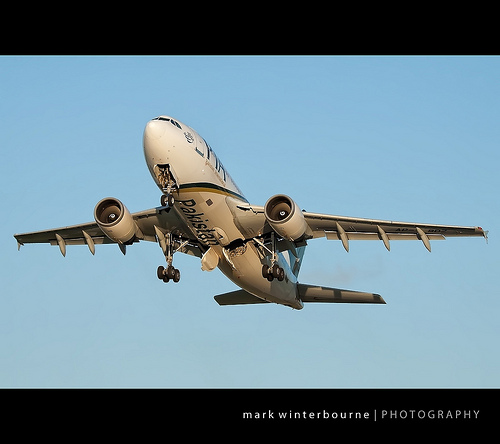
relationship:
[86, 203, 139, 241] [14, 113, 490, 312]
engine on plane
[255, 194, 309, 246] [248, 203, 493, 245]
engine by wing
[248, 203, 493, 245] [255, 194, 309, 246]
wing with engine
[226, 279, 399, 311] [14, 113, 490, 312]
tail on plane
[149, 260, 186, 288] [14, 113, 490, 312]
wheels on plane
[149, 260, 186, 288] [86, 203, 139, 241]
wheels by engine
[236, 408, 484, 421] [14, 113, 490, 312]
water on plane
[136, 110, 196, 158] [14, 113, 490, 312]
cockpit on plane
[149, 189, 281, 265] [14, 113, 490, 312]
belly of plane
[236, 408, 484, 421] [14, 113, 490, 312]
name by plane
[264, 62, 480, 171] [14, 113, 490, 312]
sky by plane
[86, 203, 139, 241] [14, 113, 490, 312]
engine of plane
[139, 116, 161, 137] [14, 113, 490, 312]
nose of plane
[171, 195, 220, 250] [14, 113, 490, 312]
name on plane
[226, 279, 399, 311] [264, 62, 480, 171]
tail by sky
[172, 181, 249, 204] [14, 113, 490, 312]
stripes on plane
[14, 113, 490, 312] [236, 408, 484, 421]
plane by water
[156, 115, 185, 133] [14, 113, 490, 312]
window by plane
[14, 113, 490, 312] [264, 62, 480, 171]
plane by sky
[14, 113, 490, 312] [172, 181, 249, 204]
plane has stripes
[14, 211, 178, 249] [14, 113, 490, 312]
wing on plane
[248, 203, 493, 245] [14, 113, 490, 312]
wing on plane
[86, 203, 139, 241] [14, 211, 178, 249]
engine by wing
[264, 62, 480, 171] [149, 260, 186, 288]
sky by wheels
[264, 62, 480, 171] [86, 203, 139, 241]
sky by engine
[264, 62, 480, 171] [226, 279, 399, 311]
sky near tail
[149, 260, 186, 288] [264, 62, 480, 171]
wheels by sky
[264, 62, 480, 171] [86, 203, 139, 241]
sky near engine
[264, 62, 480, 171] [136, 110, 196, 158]
sky near cockpit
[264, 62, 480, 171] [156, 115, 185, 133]
sky near window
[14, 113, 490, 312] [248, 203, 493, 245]
plane near wing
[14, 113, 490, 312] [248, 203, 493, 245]
plane has wing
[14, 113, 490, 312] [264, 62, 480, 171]
plane in sky